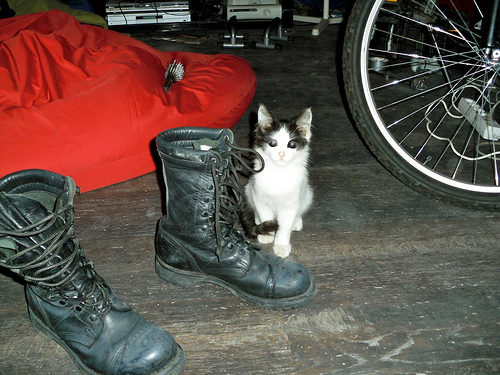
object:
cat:
[244, 103, 312, 257]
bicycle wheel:
[342, 0, 499, 209]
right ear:
[257, 104, 274, 131]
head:
[257, 103, 312, 164]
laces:
[211, 160, 222, 261]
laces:
[0, 193, 65, 237]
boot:
[154, 125, 316, 310]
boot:
[1, 168, 184, 373]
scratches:
[338, 331, 392, 347]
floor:
[1, 26, 500, 375]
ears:
[294, 107, 311, 127]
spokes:
[381, 10, 475, 44]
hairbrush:
[163, 59, 185, 91]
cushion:
[0, 9, 257, 197]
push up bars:
[217, 37, 249, 48]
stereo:
[108, 11, 191, 25]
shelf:
[108, 21, 293, 29]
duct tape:
[369, 57, 389, 72]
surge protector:
[458, 97, 499, 140]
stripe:
[369, 57, 483, 91]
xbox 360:
[228, 6, 281, 18]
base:
[293, 0, 343, 36]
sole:
[155, 258, 317, 310]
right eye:
[268, 140, 278, 148]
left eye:
[289, 142, 297, 148]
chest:
[261, 168, 301, 201]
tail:
[241, 205, 278, 238]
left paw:
[273, 243, 291, 258]